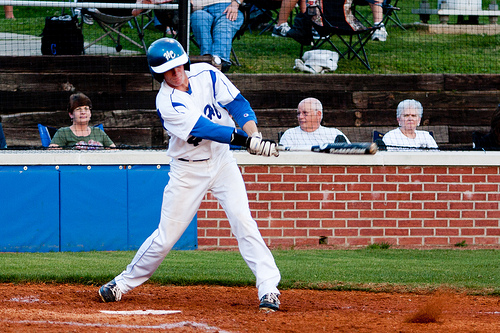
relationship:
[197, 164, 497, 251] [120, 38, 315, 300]
wall behind batter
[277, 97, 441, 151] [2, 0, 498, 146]
spectators in background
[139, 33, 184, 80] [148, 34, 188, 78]
helmet on batter's head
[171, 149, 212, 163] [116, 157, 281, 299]
belt around trousers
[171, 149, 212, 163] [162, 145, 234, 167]
belt around waist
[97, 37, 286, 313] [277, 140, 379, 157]
batter swinging bat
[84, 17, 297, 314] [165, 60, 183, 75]
batter has nose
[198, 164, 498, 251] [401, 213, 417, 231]
wall has part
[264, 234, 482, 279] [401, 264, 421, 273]
lawn has part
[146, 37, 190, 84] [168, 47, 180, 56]
helmet has part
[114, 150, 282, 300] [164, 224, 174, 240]
trousers has part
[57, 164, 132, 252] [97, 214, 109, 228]
board has part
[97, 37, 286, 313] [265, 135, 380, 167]
batter holds bat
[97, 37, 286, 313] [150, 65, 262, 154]
batter wears jersey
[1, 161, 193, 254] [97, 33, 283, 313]
padded behind batter